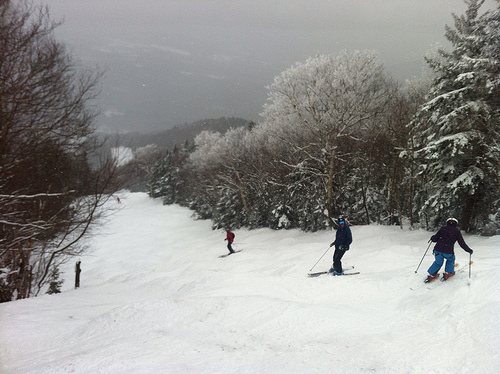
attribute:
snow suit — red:
[227, 233, 235, 250]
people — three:
[426, 216, 473, 282]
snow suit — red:
[224, 232, 234, 242]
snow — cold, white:
[1, 186, 498, 368]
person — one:
[215, 214, 249, 255]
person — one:
[394, 206, 495, 296]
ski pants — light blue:
[422, 245, 465, 276]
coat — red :
[227, 228, 233, 244]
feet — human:
[311, 260, 400, 295]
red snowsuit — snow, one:
[220, 230, 238, 244]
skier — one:
[426, 217, 470, 279]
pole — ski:
[464, 253, 474, 287]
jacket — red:
[223, 230, 235, 242]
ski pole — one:
[468, 249, 473, 279]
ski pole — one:
[415, 237, 430, 268]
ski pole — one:
[307, 242, 328, 272]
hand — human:
[469, 245, 475, 256]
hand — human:
[431, 230, 435, 238]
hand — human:
[329, 237, 334, 244]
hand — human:
[339, 243, 346, 250]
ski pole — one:
[328, 247, 339, 278]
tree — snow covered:
[417, 12, 496, 232]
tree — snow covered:
[294, 51, 390, 230]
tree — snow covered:
[9, 25, 91, 289]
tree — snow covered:
[207, 128, 263, 224]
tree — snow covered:
[170, 162, 192, 211]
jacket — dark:
[427, 221, 473, 256]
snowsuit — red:
[228, 230, 236, 249]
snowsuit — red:
[227, 230, 235, 250]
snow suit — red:
[225, 232, 234, 251]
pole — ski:
[414, 237, 435, 275]